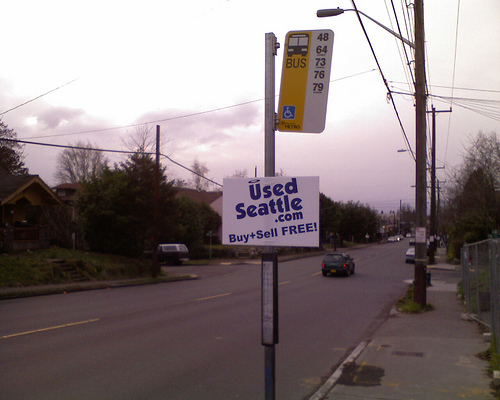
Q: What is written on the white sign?
A: Used seattle.com buy + sell free.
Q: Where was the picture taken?
A: On a street.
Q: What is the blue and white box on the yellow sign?
A: Handicap signal.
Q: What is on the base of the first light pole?
A: Sign.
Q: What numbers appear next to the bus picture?
A: 48 64 73 76 79.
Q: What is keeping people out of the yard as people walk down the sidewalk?
A: Fence.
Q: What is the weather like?
A: Cloudy.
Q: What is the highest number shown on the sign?
A: 79.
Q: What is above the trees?
A: White sky.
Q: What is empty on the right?
A: The sidewalk.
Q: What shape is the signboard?
A: Rectangular.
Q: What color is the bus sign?
A: Yellow and white.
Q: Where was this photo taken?
A: On the side of the road.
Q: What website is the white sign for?
A: UsedSeattle.com.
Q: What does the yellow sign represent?
A: A bus stop.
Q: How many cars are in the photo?
A: Three.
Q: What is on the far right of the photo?
A: A fence.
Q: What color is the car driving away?
A: Green.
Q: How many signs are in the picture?
A: Three.